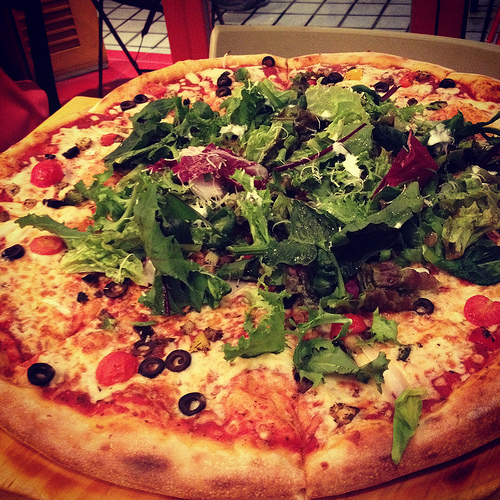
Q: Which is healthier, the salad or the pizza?
A: The salad is healthier than the pizza.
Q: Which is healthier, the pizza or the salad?
A: The salad is healthier than the pizza.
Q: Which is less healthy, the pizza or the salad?
A: The pizza is less healthy than the salad.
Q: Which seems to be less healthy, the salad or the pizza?
A: The pizza is less healthy than the salad.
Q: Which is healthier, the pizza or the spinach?
A: The spinach is healthier than the pizza.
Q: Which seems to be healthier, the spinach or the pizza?
A: The spinach is healthier than the pizza.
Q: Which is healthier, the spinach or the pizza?
A: The spinach is healthier than the pizza.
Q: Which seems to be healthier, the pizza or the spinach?
A: The spinach is healthier than the pizza.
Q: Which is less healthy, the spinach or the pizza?
A: The pizza is less healthy than the spinach.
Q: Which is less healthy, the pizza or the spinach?
A: The pizza is less healthy than the spinach.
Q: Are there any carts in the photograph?
A: No, there are no carts.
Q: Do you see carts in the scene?
A: No, there are no carts.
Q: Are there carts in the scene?
A: No, there are no carts.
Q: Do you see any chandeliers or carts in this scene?
A: No, there are no carts or chandeliers.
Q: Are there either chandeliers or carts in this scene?
A: No, there are no carts or chandeliers.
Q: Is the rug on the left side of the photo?
A: Yes, the rug is on the left of the image.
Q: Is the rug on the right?
A: No, the rug is on the left of the image.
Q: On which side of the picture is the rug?
A: The rug is on the left of the image.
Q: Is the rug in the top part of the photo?
A: Yes, the rug is in the top of the image.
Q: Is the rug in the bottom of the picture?
A: No, the rug is in the top of the image.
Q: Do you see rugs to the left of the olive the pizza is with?
A: Yes, there is a rug to the left of the olive.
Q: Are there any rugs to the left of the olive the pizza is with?
A: Yes, there is a rug to the left of the olive.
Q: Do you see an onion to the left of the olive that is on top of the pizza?
A: No, there is a rug to the left of the olive.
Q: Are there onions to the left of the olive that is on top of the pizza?
A: No, there is a rug to the left of the olive.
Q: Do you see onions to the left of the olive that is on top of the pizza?
A: No, there is a rug to the left of the olive.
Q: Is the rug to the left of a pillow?
A: No, the rug is to the left of the olive.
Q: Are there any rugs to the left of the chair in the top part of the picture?
A: Yes, there is a rug to the left of the chair.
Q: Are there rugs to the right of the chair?
A: No, the rug is to the left of the chair.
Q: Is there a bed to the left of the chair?
A: No, there is a rug to the left of the chair.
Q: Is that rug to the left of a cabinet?
A: No, the rug is to the left of the chair.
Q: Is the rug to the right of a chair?
A: No, the rug is to the left of a chair.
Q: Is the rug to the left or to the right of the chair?
A: The rug is to the left of the chair.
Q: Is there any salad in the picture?
A: Yes, there is salad.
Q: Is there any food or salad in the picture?
A: Yes, there is salad.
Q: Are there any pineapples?
A: No, there are no pineapples.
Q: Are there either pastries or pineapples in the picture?
A: No, there are no pineapples or pastries.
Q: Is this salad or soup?
A: This is salad.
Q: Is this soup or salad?
A: This is salad.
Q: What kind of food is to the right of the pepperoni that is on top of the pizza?
A: The food is salad.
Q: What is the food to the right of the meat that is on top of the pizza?
A: The food is salad.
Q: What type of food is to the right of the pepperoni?
A: The food is salad.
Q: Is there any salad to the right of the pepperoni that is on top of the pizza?
A: Yes, there is salad to the right of the pepperoni.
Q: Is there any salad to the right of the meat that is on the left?
A: Yes, there is salad to the right of the pepperoni.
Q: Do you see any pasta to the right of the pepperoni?
A: No, there is salad to the right of the pepperoni.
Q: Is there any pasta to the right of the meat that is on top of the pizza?
A: No, there is salad to the right of the pepperoni.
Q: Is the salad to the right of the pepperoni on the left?
A: Yes, the salad is to the right of the pepperoni.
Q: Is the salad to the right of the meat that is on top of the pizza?
A: Yes, the salad is to the right of the pepperoni.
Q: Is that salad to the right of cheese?
A: No, the salad is to the right of the pepperoni.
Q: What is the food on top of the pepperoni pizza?
A: The food is salad.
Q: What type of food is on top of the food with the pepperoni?
A: The food is salad.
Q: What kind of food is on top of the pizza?
A: The food is salad.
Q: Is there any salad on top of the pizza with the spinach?
A: Yes, there is salad on top of the pizza.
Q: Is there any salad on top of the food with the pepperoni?
A: Yes, there is salad on top of the pizza.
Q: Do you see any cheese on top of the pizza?
A: No, there is salad on top of the pizza.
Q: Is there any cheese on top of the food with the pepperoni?
A: No, there is salad on top of the pizza.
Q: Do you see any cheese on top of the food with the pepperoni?
A: No, there is salad on top of the pizza.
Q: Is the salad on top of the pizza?
A: Yes, the salad is on top of the pizza.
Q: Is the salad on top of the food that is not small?
A: Yes, the salad is on top of the pizza.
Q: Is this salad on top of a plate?
A: No, the salad is on top of the pizza.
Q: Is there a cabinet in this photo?
A: No, there are no cabinets.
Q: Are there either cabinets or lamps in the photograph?
A: No, there are no cabinets or lamps.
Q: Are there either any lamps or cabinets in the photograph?
A: No, there are no cabinets or lamps.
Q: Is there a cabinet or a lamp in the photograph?
A: No, there are no cabinets or lamps.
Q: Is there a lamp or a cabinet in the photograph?
A: No, there are no cabinets or lamps.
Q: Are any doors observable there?
A: Yes, there is a door.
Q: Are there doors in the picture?
A: Yes, there is a door.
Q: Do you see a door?
A: Yes, there is a door.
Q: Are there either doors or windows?
A: Yes, there is a door.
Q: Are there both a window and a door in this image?
A: No, there is a door but no windows.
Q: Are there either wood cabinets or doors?
A: Yes, there is a wood door.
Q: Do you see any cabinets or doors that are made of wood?
A: Yes, the door is made of wood.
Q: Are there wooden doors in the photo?
A: Yes, there is a wood door.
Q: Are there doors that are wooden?
A: Yes, there is a door that is wooden.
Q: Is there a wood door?
A: Yes, there is a door that is made of wood.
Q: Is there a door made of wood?
A: Yes, there is a door that is made of wood.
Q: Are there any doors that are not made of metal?
A: Yes, there is a door that is made of wood.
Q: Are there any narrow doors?
A: Yes, there is a narrow door.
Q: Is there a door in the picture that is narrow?
A: Yes, there is a door that is narrow.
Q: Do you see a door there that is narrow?
A: Yes, there is a door that is narrow.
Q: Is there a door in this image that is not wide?
A: Yes, there is a narrow door.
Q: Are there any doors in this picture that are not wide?
A: Yes, there is a narrow door.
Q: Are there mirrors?
A: No, there are no mirrors.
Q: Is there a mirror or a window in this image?
A: No, there are no mirrors or windows.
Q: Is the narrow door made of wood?
A: Yes, the door is made of wood.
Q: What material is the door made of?
A: The door is made of wood.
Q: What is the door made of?
A: The door is made of wood.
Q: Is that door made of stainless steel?
A: No, the door is made of wood.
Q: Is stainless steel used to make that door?
A: No, the door is made of wood.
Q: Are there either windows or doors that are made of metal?
A: No, there is a door but it is made of wood.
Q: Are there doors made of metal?
A: No, there is a door but it is made of wood.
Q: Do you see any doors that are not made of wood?
A: No, there is a door but it is made of wood.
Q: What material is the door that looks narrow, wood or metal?
A: The door is made of wood.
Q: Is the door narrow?
A: Yes, the door is narrow.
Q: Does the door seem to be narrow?
A: Yes, the door is narrow.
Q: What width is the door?
A: The door is narrow.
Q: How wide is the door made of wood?
A: The door is narrow.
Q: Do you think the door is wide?
A: No, the door is narrow.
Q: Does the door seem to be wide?
A: No, the door is narrow.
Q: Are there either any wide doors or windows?
A: No, there is a door but it is narrow.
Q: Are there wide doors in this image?
A: No, there is a door but it is narrow.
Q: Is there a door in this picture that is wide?
A: No, there is a door but it is narrow.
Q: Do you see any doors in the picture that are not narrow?
A: No, there is a door but it is narrow.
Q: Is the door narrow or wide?
A: The door is narrow.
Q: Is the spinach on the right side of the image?
A: Yes, the spinach is on the right of the image.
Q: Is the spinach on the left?
A: No, the spinach is on the right of the image.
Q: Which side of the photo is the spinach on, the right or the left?
A: The spinach is on the right of the image.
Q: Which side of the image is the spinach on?
A: The spinach is on the right of the image.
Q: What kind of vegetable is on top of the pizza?
A: The vegetable is spinach.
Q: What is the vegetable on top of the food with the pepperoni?
A: The vegetable is spinach.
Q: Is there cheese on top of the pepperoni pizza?
A: No, there is spinach on top of the pizza.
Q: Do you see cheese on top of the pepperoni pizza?
A: No, there is spinach on top of the pizza.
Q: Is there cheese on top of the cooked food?
A: No, there is spinach on top of the pizza.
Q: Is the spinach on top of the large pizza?
A: Yes, the spinach is on top of the pizza.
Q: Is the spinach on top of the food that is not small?
A: Yes, the spinach is on top of the pizza.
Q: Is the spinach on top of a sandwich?
A: No, the spinach is on top of the pizza.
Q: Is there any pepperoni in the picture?
A: Yes, there is pepperoni.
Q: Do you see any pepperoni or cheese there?
A: Yes, there is pepperoni.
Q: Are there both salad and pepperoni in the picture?
A: Yes, there are both pepperoni and salad.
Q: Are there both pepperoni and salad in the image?
A: Yes, there are both pepperoni and salad.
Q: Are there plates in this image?
A: No, there are no plates.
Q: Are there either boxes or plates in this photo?
A: No, there are no plates or boxes.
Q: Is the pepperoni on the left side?
A: Yes, the pepperoni is on the left of the image.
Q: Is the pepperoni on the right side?
A: No, the pepperoni is on the left of the image.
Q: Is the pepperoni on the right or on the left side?
A: The pepperoni is on the left of the image.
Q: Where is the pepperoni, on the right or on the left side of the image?
A: The pepperoni is on the left of the image.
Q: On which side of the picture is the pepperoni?
A: The pepperoni is on the left of the image.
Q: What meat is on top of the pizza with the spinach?
A: The meat is pepperoni.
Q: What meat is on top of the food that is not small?
A: The meat is pepperoni.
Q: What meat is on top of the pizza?
A: The meat is pepperoni.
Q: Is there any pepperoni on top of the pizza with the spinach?
A: Yes, there is pepperoni on top of the pizza.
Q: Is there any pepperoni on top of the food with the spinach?
A: Yes, there is pepperoni on top of the pizza.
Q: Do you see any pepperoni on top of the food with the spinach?
A: Yes, there is pepperoni on top of the pizza.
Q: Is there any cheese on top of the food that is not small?
A: No, there is pepperoni on top of the pizza.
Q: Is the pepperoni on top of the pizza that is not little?
A: Yes, the pepperoni is on top of the pizza.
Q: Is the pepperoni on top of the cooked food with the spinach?
A: Yes, the pepperoni is on top of the pizza.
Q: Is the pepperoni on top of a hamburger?
A: No, the pepperoni is on top of the pizza.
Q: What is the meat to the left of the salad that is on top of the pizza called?
A: The meat is pepperoni.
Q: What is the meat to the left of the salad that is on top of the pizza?
A: The meat is pepperoni.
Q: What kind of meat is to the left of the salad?
A: The meat is pepperoni.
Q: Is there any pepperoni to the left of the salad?
A: Yes, there is pepperoni to the left of the salad.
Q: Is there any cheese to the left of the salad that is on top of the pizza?
A: No, there is pepperoni to the left of the salad.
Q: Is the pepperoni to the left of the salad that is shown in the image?
A: Yes, the pepperoni is to the left of the salad.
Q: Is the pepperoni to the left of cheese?
A: No, the pepperoni is to the left of the salad.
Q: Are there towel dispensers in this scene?
A: No, there are no towel dispensers.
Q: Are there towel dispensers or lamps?
A: No, there are no towel dispensers or lamps.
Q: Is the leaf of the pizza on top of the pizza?
A: Yes, the leaf is on top of the pizza.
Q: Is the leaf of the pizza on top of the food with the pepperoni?
A: Yes, the leaf is on top of the pizza.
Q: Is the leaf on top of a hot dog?
A: No, the leaf is on top of the pizza.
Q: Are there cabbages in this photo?
A: No, there are no cabbages.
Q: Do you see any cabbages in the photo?
A: No, there are no cabbages.